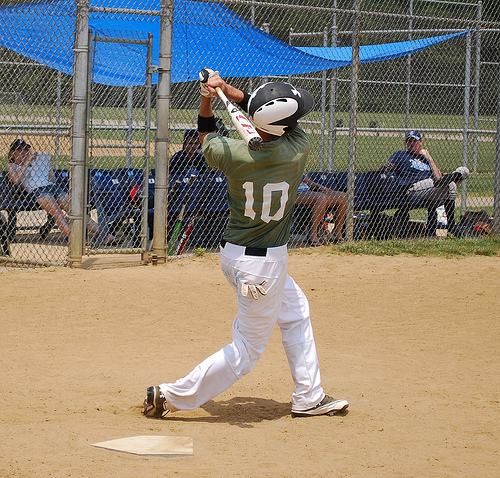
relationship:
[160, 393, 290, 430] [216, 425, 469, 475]
shadow on ground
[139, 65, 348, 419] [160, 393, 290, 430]
player has shadow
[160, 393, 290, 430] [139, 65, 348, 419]
shadow of player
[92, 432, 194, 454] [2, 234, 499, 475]
home plate on baseball field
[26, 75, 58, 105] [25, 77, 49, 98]
leaves on tree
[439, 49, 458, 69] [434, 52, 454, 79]
leaves on tree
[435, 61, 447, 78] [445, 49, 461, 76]
leaves on tree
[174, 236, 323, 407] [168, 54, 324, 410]
pants on player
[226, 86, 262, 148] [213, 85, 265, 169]
bat held by player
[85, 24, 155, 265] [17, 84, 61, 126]
door on a fence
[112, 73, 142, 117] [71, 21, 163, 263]
chain between fence